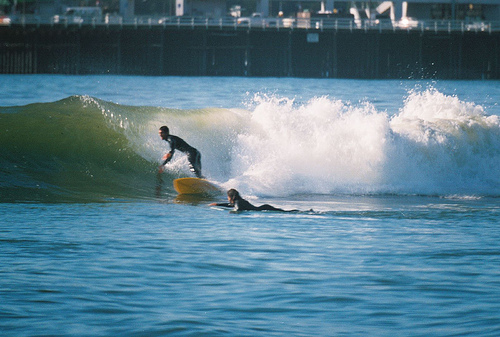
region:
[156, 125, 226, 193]
man on a yellow surfboard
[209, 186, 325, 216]
surfer paddling out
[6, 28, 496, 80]
long bridge over the water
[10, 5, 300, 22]
traffic on the bridge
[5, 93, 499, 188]
large crashing wave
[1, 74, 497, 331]
clear blue water where to surf in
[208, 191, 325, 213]
person laying on a surfboard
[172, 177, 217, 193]
yellow surfboard in water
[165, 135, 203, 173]
black wet suit on man catching wave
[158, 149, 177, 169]
man's arms extended for balance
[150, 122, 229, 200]
person riding on a yellow surf board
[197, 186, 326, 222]
person lying down on a surfboard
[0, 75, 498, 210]
large wave in the ocean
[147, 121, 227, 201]
person wearing a wet suit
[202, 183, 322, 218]
person wearing a wet suit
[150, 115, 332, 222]
two people surfing in the water together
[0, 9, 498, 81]
large seawall with metal railing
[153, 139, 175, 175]
arm of a person who is surfing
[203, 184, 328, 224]
woman has brown hair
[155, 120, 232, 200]
man has short hair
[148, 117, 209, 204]
a guy surfing on a wave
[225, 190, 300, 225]
a girl paddling on a surf board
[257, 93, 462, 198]
a white wave crashing in the ocean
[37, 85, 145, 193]
a small wave forming in the ocean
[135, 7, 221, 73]
the ledge of a pier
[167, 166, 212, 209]
a long yellow surf board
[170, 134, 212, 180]
a blue and white surf suit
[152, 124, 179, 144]
the smiling face of a surfer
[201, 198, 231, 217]
a womans arms paddling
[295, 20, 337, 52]
a white sign stuck on the pier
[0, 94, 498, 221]
Large transparent wave.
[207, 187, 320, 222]
Female surfer laying on board.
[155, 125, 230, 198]
Male surfer standing on surf board.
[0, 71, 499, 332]
Two people surfing in the water.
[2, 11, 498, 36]
Long white fence.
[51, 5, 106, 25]
White van with letters on it.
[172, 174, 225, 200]
Yellow surf board in water.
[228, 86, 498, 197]
Large white splashes of water.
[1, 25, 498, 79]
Wooden poles of a board walk.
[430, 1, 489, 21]
Windows on side of building.